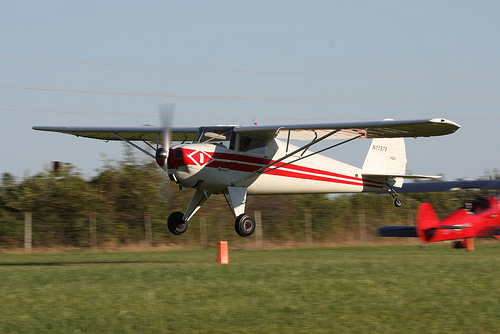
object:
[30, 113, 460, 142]
wing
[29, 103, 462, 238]
planes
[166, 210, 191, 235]
wheel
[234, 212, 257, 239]
wheel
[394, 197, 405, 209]
wheel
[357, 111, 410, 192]
rudder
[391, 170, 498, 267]
plane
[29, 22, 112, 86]
clouds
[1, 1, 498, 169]
sky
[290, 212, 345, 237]
fence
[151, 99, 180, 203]
propeller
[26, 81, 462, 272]
plane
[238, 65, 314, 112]
clouds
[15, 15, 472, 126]
sky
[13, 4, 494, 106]
sky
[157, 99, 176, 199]
propeller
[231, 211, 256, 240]
tire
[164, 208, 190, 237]
tire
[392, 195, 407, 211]
tire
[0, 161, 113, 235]
tree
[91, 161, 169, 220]
tree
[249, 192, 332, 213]
tree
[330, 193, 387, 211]
tree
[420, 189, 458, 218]
tree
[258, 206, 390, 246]
fence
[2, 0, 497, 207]
sky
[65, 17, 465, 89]
skies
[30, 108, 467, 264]
plane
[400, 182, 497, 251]
plane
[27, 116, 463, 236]
airplane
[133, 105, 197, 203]
propeller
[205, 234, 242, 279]
cone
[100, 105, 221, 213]
propeller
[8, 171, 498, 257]
trees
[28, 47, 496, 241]
airplane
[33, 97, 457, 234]
airplane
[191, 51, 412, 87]
bad setence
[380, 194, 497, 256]
plane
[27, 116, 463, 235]
white plane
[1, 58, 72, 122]
clouds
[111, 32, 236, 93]
clouds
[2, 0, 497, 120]
sky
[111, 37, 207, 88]
clouds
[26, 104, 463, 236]
plane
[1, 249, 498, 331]
ground level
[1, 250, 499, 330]
ground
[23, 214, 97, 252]
posts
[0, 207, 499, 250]
fence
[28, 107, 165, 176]
wing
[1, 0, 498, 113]
air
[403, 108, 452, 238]
tail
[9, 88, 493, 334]
airport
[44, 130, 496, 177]
group